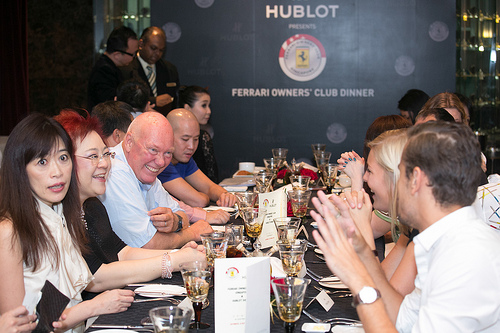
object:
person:
[1, 113, 136, 333]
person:
[51, 108, 211, 294]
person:
[160, 108, 240, 209]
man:
[97, 111, 214, 251]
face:
[130, 122, 175, 182]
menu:
[213, 256, 271, 331]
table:
[85, 167, 368, 333]